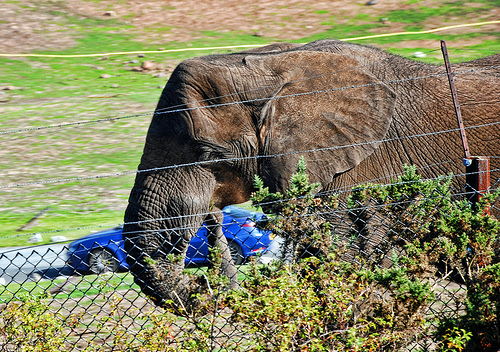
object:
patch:
[2, 6, 76, 55]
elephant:
[123, 38, 499, 349]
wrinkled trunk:
[123, 153, 232, 317]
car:
[65, 199, 274, 275]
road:
[0, 209, 287, 285]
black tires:
[88, 248, 120, 275]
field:
[0, 0, 500, 247]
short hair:
[197, 38, 367, 60]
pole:
[439, 40, 499, 352]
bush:
[0, 153, 495, 351]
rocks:
[29, 233, 45, 244]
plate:
[341, 162, 500, 352]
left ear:
[243, 49, 398, 200]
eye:
[196, 150, 215, 162]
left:
[215, 90, 447, 169]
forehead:
[143, 57, 207, 155]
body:
[254, 39, 500, 245]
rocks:
[140, 60, 154, 68]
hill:
[0, 0, 177, 81]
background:
[3, 0, 498, 164]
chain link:
[2, 41, 500, 352]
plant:
[201, 155, 346, 351]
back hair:
[186, 37, 401, 67]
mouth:
[205, 181, 237, 213]